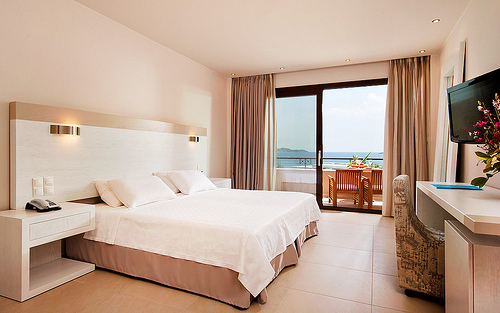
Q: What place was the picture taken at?
A: It was taken at the hotel room.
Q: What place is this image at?
A: It is at the hotel room.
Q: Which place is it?
A: It is a hotel room.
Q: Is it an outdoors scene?
A: Yes, it is outdoors.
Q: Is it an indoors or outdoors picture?
A: It is outdoors.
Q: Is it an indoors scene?
A: No, it is outdoors.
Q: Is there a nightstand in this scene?
A: Yes, there is a nightstand.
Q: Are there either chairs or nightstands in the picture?
A: Yes, there is a nightstand.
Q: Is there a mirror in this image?
A: No, there are no mirrors.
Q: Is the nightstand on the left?
A: Yes, the nightstand is on the left of the image.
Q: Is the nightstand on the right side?
A: No, the nightstand is on the left of the image.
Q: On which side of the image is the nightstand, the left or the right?
A: The nightstand is on the left of the image.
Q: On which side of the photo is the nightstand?
A: The nightstand is on the left of the image.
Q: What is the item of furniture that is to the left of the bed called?
A: The piece of furniture is a nightstand.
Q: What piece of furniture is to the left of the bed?
A: The piece of furniture is a nightstand.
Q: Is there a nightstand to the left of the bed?
A: Yes, there is a nightstand to the left of the bed.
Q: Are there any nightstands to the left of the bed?
A: Yes, there is a nightstand to the left of the bed.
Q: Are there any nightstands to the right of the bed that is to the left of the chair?
A: No, the nightstand is to the left of the bed.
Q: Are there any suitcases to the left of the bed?
A: No, there is a nightstand to the left of the bed.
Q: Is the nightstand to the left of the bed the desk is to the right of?
A: Yes, the nightstand is to the left of the bed.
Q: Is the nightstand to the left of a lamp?
A: No, the nightstand is to the left of the bed.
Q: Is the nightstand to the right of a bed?
A: No, the nightstand is to the left of a bed.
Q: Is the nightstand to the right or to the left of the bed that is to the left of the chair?
A: The nightstand is to the left of the bed.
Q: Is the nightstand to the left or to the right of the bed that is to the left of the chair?
A: The nightstand is to the left of the bed.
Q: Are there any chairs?
A: Yes, there is a chair.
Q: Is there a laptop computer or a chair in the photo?
A: Yes, there is a chair.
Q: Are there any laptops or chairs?
A: Yes, there is a chair.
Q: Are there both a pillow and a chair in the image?
A: Yes, there are both a chair and a pillow.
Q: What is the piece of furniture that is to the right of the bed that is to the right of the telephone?
A: The piece of furniture is a chair.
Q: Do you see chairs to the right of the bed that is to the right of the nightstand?
A: Yes, there is a chair to the right of the bed.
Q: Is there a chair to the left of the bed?
A: No, the chair is to the right of the bed.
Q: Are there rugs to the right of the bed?
A: No, there is a chair to the right of the bed.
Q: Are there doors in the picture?
A: Yes, there is a door.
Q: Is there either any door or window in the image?
A: Yes, there is a door.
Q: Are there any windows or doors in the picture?
A: Yes, there is a door.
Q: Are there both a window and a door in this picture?
A: Yes, there are both a door and a window.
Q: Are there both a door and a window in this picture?
A: Yes, there are both a door and a window.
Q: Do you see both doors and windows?
A: Yes, there are both a door and windows.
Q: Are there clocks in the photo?
A: No, there are no clocks.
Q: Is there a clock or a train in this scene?
A: No, there are no clocks or trains.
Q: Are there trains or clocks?
A: No, there are no clocks or trains.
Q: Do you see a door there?
A: Yes, there are doors.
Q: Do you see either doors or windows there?
A: Yes, there are doors.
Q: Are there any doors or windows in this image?
A: Yes, there are doors.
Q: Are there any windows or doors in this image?
A: Yes, there are doors.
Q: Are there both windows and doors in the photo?
A: Yes, there are both doors and a window.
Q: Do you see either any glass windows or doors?
A: Yes, there are glass doors.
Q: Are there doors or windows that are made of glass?
A: Yes, the doors are made of glass.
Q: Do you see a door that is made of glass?
A: Yes, there are doors that are made of glass.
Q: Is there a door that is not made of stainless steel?
A: Yes, there are doors that are made of glass.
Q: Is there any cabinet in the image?
A: No, there are no cabinets.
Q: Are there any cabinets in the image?
A: No, there are no cabinets.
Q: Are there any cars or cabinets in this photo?
A: No, there are no cabinets or cars.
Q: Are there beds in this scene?
A: Yes, there is a bed.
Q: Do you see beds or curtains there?
A: Yes, there is a bed.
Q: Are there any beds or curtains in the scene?
A: Yes, there is a bed.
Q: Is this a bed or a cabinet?
A: This is a bed.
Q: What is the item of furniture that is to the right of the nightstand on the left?
A: The piece of furniture is a bed.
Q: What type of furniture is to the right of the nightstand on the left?
A: The piece of furniture is a bed.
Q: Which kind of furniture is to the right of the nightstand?
A: The piece of furniture is a bed.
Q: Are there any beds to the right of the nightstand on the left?
A: Yes, there is a bed to the right of the nightstand.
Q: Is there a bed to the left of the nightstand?
A: No, the bed is to the right of the nightstand.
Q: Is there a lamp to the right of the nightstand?
A: No, there is a bed to the right of the nightstand.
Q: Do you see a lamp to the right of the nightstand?
A: No, there is a bed to the right of the nightstand.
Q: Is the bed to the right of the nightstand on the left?
A: Yes, the bed is to the right of the nightstand.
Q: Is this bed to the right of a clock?
A: No, the bed is to the right of the nightstand.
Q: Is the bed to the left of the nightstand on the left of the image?
A: No, the bed is to the right of the nightstand.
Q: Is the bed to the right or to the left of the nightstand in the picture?
A: The bed is to the right of the nightstand.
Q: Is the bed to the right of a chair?
A: No, the bed is to the left of a chair.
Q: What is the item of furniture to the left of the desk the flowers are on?
A: The piece of furniture is a bed.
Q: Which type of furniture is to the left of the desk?
A: The piece of furniture is a bed.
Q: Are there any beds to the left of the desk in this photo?
A: Yes, there is a bed to the left of the desk.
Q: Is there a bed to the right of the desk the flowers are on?
A: No, the bed is to the left of the desk.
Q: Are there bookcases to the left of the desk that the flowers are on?
A: No, there is a bed to the left of the desk.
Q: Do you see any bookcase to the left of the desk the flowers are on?
A: No, there is a bed to the left of the desk.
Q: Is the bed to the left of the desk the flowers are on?
A: Yes, the bed is to the left of the desk.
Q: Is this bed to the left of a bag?
A: No, the bed is to the left of the desk.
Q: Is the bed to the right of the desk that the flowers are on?
A: No, the bed is to the left of the desk.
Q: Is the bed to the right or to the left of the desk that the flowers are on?
A: The bed is to the left of the desk.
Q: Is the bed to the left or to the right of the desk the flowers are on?
A: The bed is to the left of the desk.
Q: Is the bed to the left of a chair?
A: Yes, the bed is to the left of a chair.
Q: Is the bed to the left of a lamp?
A: No, the bed is to the left of a chair.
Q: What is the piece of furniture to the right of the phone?
A: The piece of furniture is a bed.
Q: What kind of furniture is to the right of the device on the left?
A: The piece of furniture is a bed.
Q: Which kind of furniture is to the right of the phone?
A: The piece of furniture is a bed.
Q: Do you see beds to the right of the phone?
A: Yes, there is a bed to the right of the phone.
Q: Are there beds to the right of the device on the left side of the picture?
A: Yes, there is a bed to the right of the phone.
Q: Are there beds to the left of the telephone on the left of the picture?
A: No, the bed is to the right of the telephone.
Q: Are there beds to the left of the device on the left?
A: No, the bed is to the right of the telephone.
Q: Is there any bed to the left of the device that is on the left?
A: No, the bed is to the right of the telephone.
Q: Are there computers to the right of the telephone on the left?
A: No, there is a bed to the right of the telephone.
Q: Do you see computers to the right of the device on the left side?
A: No, there is a bed to the right of the telephone.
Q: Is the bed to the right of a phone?
A: Yes, the bed is to the right of a phone.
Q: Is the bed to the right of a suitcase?
A: No, the bed is to the right of a phone.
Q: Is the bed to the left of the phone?
A: No, the bed is to the right of the phone.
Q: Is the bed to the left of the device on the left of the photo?
A: No, the bed is to the right of the phone.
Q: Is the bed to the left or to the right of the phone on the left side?
A: The bed is to the right of the phone.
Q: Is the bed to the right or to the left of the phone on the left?
A: The bed is to the right of the phone.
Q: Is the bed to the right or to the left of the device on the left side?
A: The bed is to the right of the phone.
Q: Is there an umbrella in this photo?
A: No, there are no umbrellas.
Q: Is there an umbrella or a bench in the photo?
A: No, there are no umbrellas or benches.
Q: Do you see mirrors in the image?
A: No, there are no mirrors.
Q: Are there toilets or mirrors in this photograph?
A: No, there are no mirrors or toilets.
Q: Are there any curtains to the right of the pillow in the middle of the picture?
A: Yes, there is a curtain to the right of the pillow.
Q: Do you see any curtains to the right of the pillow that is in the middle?
A: Yes, there is a curtain to the right of the pillow.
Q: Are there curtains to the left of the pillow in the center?
A: No, the curtain is to the right of the pillow.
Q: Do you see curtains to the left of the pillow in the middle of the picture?
A: No, the curtain is to the right of the pillow.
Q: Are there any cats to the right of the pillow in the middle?
A: No, there is a curtain to the right of the pillow.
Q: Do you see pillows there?
A: Yes, there is a pillow.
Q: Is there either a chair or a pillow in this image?
A: Yes, there is a pillow.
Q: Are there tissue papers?
A: No, there are no tissue papers.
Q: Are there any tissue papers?
A: No, there are no tissue papers.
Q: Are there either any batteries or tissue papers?
A: No, there are no tissue papers or batteries.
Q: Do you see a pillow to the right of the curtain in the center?
A: No, the pillow is to the left of the curtain.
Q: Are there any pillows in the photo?
A: Yes, there is a pillow.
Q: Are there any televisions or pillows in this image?
A: Yes, there is a pillow.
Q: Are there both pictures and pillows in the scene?
A: No, there is a pillow but no pictures.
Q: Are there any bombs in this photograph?
A: No, there are no bombs.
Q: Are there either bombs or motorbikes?
A: No, there are no bombs or motorbikes.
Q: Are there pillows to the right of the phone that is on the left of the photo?
A: Yes, there is a pillow to the right of the phone.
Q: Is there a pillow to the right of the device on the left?
A: Yes, there is a pillow to the right of the phone.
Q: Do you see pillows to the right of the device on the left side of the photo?
A: Yes, there is a pillow to the right of the phone.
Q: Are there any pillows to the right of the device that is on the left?
A: Yes, there is a pillow to the right of the phone.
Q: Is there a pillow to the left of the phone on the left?
A: No, the pillow is to the right of the telephone.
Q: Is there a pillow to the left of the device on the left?
A: No, the pillow is to the right of the telephone.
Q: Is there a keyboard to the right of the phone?
A: No, there is a pillow to the right of the phone.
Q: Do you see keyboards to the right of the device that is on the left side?
A: No, there is a pillow to the right of the phone.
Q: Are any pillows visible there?
A: Yes, there is a pillow.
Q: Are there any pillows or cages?
A: Yes, there is a pillow.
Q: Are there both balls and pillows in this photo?
A: No, there is a pillow but no balls.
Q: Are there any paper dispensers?
A: No, there are no paper dispensers.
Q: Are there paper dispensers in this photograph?
A: No, there are no paper dispensers.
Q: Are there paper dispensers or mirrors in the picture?
A: No, there are no paper dispensers or mirrors.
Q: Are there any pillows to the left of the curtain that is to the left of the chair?
A: Yes, there is a pillow to the left of the curtain.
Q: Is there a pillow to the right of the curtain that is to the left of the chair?
A: No, the pillow is to the left of the curtain.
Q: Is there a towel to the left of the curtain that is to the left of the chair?
A: No, there is a pillow to the left of the curtain.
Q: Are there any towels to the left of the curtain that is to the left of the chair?
A: No, there is a pillow to the left of the curtain.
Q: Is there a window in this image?
A: Yes, there is a window.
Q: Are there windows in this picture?
A: Yes, there is a window.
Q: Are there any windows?
A: Yes, there is a window.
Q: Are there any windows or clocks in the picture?
A: Yes, there is a window.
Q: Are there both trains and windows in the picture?
A: No, there is a window but no trains.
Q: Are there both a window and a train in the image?
A: No, there is a window but no trains.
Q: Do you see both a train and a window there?
A: No, there is a window but no trains.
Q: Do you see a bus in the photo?
A: No, there are no buses.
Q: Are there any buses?
A: No, there are no buses.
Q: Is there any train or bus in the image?
A: No, there are no buses or trains.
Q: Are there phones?
A: Yes, there is a phone.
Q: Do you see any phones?
A: Yes, there is a phone.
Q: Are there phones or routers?
A: Yes, there is a phone.